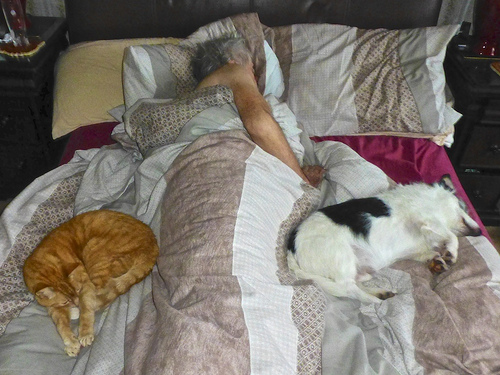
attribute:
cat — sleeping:
[5, 195, 187, 332]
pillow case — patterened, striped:
[268, 15, 475, 164]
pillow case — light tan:
[101, 32, 474, 137]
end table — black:
[444, 42, 499, 175]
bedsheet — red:
[32, 128, 460, 366]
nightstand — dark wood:
[3, 15, 59, 68]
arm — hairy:
[217, 62, 327, 192]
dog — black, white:
[298, 149, 498, 316]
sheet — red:
[1, 136, 491, 371]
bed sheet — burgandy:
[56, 121, 494, 241]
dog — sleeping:
[273, 145, 488, 321]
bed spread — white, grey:
[0, 127, 498, 373]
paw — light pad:
[282, 171, 498, 320]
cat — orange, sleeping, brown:
[18, 203, 158, 359]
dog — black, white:
[287, 176, 482, 299]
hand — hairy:
[296, 158, 326, 186]